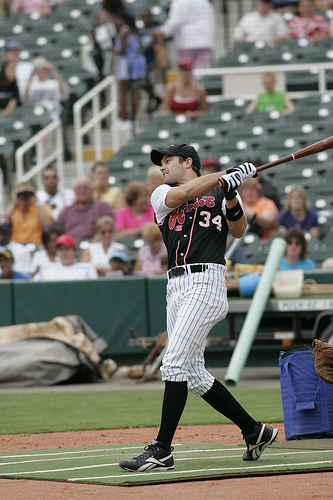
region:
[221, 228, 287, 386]
Gray pipe leaning against the trailer.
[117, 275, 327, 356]
Trailer in the background.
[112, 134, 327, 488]
Player warming up to bat.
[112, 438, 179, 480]
Black shoe on the foot.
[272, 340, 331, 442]
Blue bag on the ground.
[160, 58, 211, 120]
Red hat on woman.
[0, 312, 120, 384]
Gray tarp on the ground.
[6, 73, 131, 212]
Hand railing on the steps.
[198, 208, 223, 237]
Number on shirt.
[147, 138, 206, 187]
black hat on player.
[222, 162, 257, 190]
a pair of white and black baseball gloves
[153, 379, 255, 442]
a pair of knee high baseball socks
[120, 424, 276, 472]
a pair of black and whtie baseball cleats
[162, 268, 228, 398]
white with black striped baseball uniform pants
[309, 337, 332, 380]
a brown baseball catcher's mit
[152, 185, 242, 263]
a black, white, and red baseball jersey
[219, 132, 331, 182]
a dark brown baseball bat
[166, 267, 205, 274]
a black leather baseball belt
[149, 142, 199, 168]
a black baseball cap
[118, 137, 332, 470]
a player swinging a baseball bat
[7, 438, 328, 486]
a green and white mat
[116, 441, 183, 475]
a black and white cleat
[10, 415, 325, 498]
a patch of red dirt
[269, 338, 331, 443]
a blue fabric bin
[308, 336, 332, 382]
a leather baseball glove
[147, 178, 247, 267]
a black jersey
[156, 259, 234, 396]
a pair of striped pants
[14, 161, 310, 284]
a group of spectators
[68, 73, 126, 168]
a white hand rail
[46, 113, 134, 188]
a set of stairs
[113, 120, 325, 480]
Man playing baseball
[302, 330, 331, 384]
A catcher's glove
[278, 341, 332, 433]
Blue bag next to the catcher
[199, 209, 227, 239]
Man is number 34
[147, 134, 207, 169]
Man is wearing a hat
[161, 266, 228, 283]
Man is wearing a belt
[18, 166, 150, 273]
Small audience watching the game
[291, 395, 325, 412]
Handle for the blue bag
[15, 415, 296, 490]
Standing on a green mat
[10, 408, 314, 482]
The green mat is sitting on dirt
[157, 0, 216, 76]
Person in white jacket standing on stairs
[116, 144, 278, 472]
Male baseball player assigned number 34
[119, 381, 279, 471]
Black knee-high stockings in black and white sneakers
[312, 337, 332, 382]
Edge of a brown baseball glove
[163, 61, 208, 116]
Woman in a red hat and red tank top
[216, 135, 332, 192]
Two hands gripping a baseball bat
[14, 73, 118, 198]
Two white railings along the bleacher stairs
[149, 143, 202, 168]
Black baseball cap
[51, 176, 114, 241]
Older man in a purple shirt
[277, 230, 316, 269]
Woman in blue shirt and sunglasses